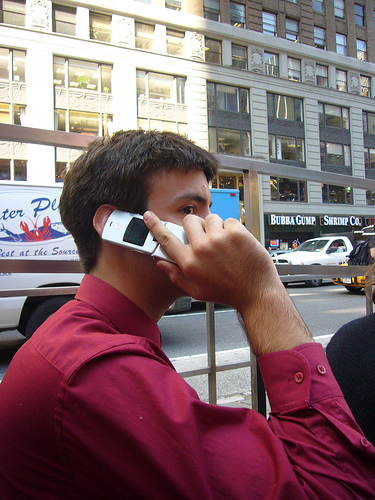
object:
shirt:
[0, 273, 375, 500]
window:
[262, 49, 279, 77]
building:
[1, 0, 375, 273]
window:
[229, 3, 247, 29]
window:
[335, 67, 348, 93]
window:
[336, 32, 348, 57]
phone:
[101, 209, 189, 263]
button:
[318, 365, 327, 375]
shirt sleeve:
[56, 342, 374, 497]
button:
[294, 372, 303, 383]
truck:
[270, 236, 354, 286]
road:
[1, 259, 372, 418]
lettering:
[0, 180, 67, 220]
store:
[264, 202, 375, 251]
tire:
[26, 298, 76, 342]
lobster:
[0, 214, 71, 243]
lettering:
[0, 237, 75, 265]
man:
[0, 127, 369, 500]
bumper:
[270, 256, 293, 265]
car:
[331, 242, 375, 292]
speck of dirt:
[137, 413, 145, 419]